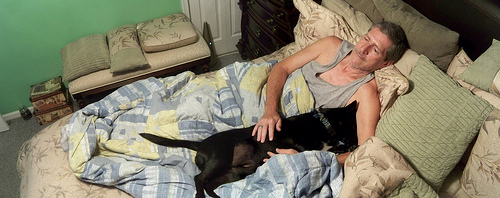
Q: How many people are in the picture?
A: One.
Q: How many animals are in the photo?
A: One.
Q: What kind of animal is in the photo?
A: Dog.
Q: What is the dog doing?
A: Sleeping.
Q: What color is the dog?
A: Black.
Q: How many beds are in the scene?
A: One.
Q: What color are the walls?
A: Green.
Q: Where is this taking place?
A: In a bedroom.